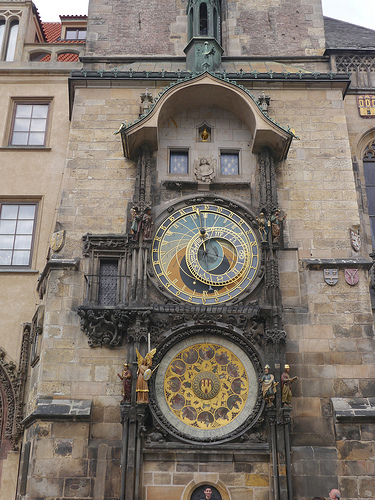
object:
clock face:
[151, 201, 260, 305]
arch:
[179, 469, 235, 500]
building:
[2, 0, 375, 500]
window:
[7, 96, 50, 151]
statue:
[193, 150, 217, 181]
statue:
[259, 364, 279, 406]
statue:
[281, 364, 299, 409]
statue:
[256, 210, 271, 243]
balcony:
[23, 41, 83, 64]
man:
[202, 487, 212, 500]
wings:
[135, 348, 143, 366]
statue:
[135, 344, 157, 405]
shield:
[144, 368, 152, 381]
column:
[267, 414, 296, 499]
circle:
[147, 331, 269, 439]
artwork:
[164, 343, 247, 428]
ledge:
[68, 66, 352, 85]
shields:
[345, 266, 360, 286]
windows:
[169, 146, 189, 176]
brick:
[86, 0, 325, 60]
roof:
[323, 13, 374, 55]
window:
[221, 153, 238, 177]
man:
[325, 488, 340, 500]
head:
[203, 485, 214, 499]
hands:
[196, 211, 207, 252]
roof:
[32, 12, 88, 62]